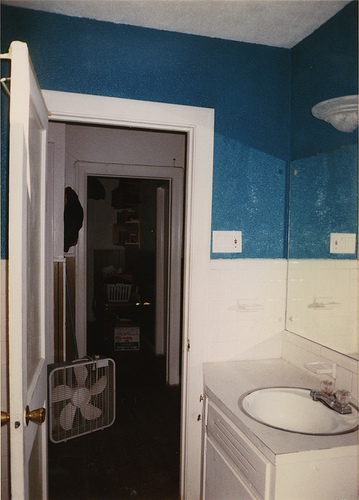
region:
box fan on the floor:
[45, 356, 127, 448]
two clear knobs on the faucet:
[316, 378, 350, 407]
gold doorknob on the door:
[21, 402, 54, 429]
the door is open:
[8, 52, 189, 498]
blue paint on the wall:
[0, 1, 357, 260]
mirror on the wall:
[278, 146, 355, 363]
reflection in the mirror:
[286, 154, 357, 362]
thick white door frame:
[71, 151, 185, 387]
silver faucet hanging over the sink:
[305, 389, 332, 409]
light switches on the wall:
[211, 227, 245, 253]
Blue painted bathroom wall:
[2, 2, 356, 263]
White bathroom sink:
[234, 379, 356, 436]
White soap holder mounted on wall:
[302, 357, 337, 380]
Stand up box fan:
[45, 356, 117, 444]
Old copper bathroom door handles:
[0, 404, 47, 428]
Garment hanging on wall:
[64, 181, 86, 254]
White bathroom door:
[9, 40, 51, 498]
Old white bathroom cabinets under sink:
[201, 387, 356, 496]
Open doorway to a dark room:
[82, 173, 168, 382]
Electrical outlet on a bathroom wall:
[212, 228, 241, 253]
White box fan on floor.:
[49, 365, 114, 418]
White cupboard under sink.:
[205, 450, 235, 494]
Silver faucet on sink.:
[311, 383, 331, 406]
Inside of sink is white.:
[268, 398, 301, 424]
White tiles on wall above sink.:
[285, 338, 302, 352]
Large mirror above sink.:
[299, 292, 341, 323]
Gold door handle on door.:
[23, 403, 47, 415]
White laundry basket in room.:
[97, 278, 141, 300]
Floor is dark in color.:
[73, 440, 129, 473]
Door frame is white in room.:
[176, 286, 202, 390]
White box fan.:
[45, 354, 116, 443]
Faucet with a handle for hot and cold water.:
[307, 379, 351, 415]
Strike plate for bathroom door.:
[184, 336, 193, 351]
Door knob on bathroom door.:
[0, 404, 45, 427]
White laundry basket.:
[104, 276, 132, 304]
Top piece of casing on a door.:
[74, 159, 183, 180]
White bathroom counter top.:
[200, 354, 355, 466]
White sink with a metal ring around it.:
[237, 383, 358, 437]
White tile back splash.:
[278, 327, 358, 397]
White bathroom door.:
[6, 40, 51, 498]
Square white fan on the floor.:
[46, 354, 122, 443]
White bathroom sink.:
[204, 362, 355, 446]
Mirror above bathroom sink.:
[275, 90, 354, 360]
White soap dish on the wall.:
[303, 357, 336, 380]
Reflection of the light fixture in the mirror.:
[310, 92, 357, 134]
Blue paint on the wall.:
[10, 43, 288, 96]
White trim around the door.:
[37, 84, 217, 362]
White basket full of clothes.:
[102, 273, 133, 303]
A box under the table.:
[109, 317, 142, 351]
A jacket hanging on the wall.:
[62, 181, 88, 256]